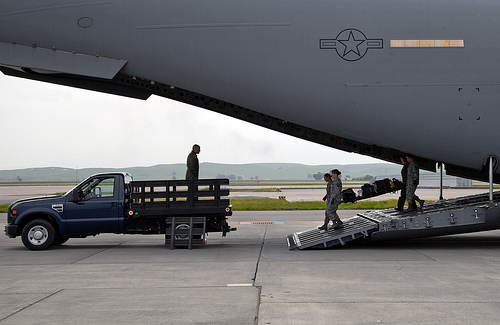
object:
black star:
[337, 30, 365, 57]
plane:
[0, 0, 499, 183]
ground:
[0, 181, 499, 324]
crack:
[252, 224, 268, 324]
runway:
[0, 211, 496, 323]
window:
[69, 176, 115, 202]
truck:
[4, 172, 237, 251]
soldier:
[326, 169, 344, 229]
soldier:
[317, 173, 337, 231]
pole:
[489, 156, 493, 203]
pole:
[437, 162, 443, 200]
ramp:
[277, 190, 497, 255]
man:
[185, 144, 200, 201]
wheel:
[20, 219, 55, 251]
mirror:
[70, 188, 81, 202]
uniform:
[326, 177, 342, 220]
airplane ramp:
[286, 191, 500, 251]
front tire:
[21, 219, 56, 251]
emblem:
[318, 27, 384, 61]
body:
[341, 178, 405, 204]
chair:
[165, 216, 206, 250]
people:
[317, 154, 425, 230]